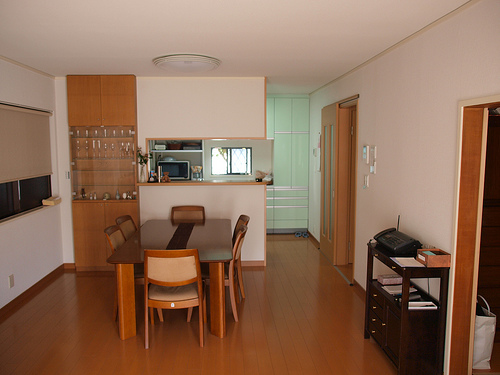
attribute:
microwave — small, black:
[157, 159, 191, 180]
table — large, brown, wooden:
[106, 218, 233, 340]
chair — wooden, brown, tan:
[143, 249, 206, 349]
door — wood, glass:
[321, 105, 339, 266]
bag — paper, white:
[474, 293, 498, 371]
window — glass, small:
[211, 147, 253, 176]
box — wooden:
[416, 247, 452, 267]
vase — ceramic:
[140, 165, 147, 183]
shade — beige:
[1, 100, 52, 184]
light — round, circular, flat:
[152, 53, 220, 74]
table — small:
[363, 236, 449, 375]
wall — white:
[306, 0, 499, 373]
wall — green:
[267, 94, 312, 235]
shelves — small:
[70, 125, 139, 199]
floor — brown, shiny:
[1, 233, 499, 375]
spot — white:
[170, 301, 176, 307]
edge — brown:
[311, 2, 471, 94]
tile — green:
[266, 92, 312, 234]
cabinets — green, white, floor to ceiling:
[266, 92, 312, 232]